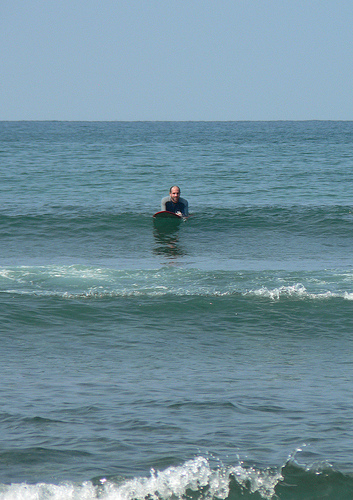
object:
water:
[1, 120, 353, 500]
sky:
[0, 0, 352, 122]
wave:
[0, 459, 352, 499]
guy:
[160, 185, 188, 218]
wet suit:
[161, 196, 188, 216]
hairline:
[170, 185, 180, 192]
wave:
[0, 265, 351, 303]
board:
[152, 211, 181, 218]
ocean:
[0, 122, 351, 500]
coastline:
[0, 120, 353, 123]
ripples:
[0, 208, 352, 232]